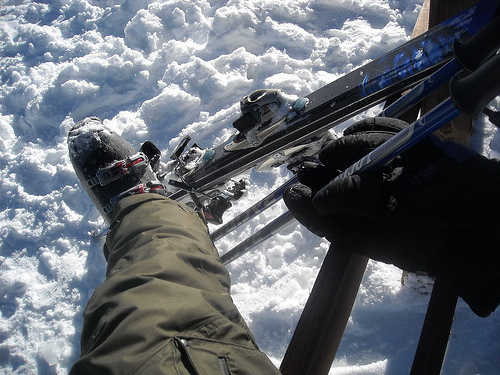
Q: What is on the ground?
A: Snow.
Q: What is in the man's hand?
A: Ski pole.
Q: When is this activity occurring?
A: Winter.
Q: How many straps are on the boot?
A: 2.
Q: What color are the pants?
A: Green.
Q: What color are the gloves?
A: Black.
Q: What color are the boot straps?
A: Red.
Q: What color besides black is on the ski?
A: Blue.